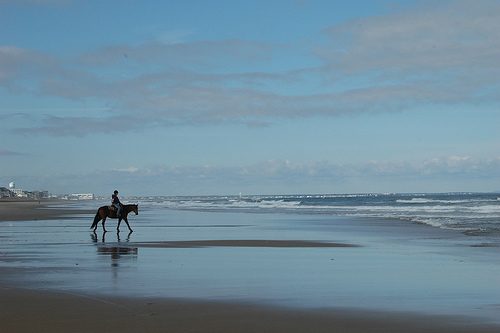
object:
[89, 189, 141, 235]
person horse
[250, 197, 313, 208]
waves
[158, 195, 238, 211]
sea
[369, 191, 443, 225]
ocean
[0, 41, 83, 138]
grey clouds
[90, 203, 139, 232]
horse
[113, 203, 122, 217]
jeans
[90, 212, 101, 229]
tail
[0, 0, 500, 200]
sky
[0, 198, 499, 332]
sand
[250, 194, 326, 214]
sea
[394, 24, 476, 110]
clouds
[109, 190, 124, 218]
man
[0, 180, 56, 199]
buildings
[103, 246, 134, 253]
water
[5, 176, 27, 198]
tank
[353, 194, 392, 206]
water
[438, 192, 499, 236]
ocean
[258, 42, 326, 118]
clouds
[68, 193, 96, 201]
building